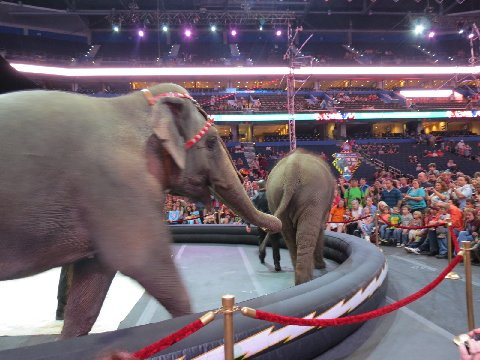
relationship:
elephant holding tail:
[0, 82, 281, 342] [259, 187, 294, 264]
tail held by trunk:
[259, 187, 294, 264] [212, 132, 283, 234]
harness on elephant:
[141, 81, 215, 157] [0, 82, 281, 342]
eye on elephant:
[207, 135, 218, 149] [0, 82, 281, 342]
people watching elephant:
[0, 41, 478, 263] [0, 82, 281, 342]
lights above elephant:
[8, 15, 479, 121] [0, 82, 281, 342]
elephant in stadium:
[0, 82, 281, 342] [0, 1, 480, 358]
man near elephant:
[246, 179, 282, 271] [259, 149, 334, 282]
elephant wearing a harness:
[0, 82, 281, 342] [141, 81, 215, 157]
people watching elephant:
[0, 41, 478, 263] [259, 149, 334, 282]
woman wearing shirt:
[403, 177, 424, 214] [405, 187, 428, 210]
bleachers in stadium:
[0, 34, 479, 122] [0, 1, 480, 358]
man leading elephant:
[246, 179, 282, 271] [259, 149, 334, 282]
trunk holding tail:
[212, 132, 283, 234] [259, 187, 294, 264]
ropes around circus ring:
[132, 210, 464, 358] [0, 223, 388, 359]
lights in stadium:
[8, 15, 479, 121] [0, 1, 480, 358]